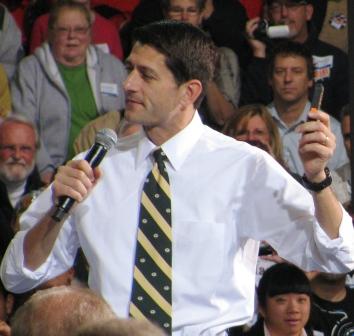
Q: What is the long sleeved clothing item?
A: The clothing item is a shirt.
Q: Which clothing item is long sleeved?
A: The clothing item is a shirt.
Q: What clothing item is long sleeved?
A: The clothing item is a shirt.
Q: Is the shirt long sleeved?
A: Yes, the shirt is long sleeved.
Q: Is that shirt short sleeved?
A: No, the shirt is long sleeved.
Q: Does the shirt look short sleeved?
A: No, the shirt is long sleeved.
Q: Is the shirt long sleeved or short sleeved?
A: The shirt is long sleeved.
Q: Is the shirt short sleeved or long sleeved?
A: The shirt is long sleeved.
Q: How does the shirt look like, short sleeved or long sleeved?
A: The shirt is long sleeved.